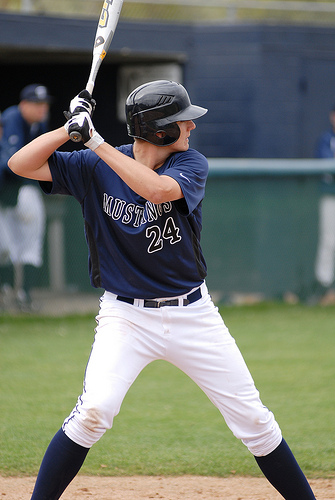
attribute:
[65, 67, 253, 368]
boy — batting, playing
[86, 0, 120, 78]
bat — silver, grey, black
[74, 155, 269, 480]
uniform — blue, white, stained, nike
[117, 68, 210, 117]
helmet — black, shinning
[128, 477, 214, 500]
ground — brown, sandy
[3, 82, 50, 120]
man — far, close